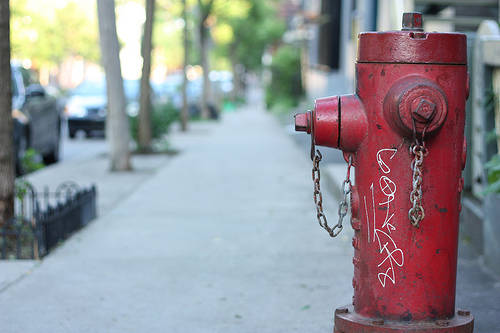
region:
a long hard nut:
[279, 70, 312, 147]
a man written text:
[377, 147, 427, 294]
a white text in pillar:
[363, 130, 422, 317]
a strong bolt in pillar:
[393, 82, 443, 128]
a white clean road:
[16, 80, 343, 327]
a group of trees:
[95, 25, 237, 128]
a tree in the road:
[88, 10, 147, 204]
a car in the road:
[50, 71, 147, 143]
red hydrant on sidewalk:
[304, 19, 471, 323]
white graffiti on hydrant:
[350, 144, 443, 309]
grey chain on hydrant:
[383, 116, 427, 254]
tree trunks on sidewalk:
[97, 2, 172, 198]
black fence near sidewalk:
[26, 152, 123, 276]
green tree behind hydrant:
[256, 57, 303, 140]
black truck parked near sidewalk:
[1, 66, 77, 178]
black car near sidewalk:
[47, 50, 142, 151]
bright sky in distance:
[35, 4, 140, 56]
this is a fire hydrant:
[274, 7, 480, 331]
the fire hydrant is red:
[241, 18, 478, 328]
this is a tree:
[89, 9, 134, 180]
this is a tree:
[129, 4, 161, 152]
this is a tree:
[170, 13, 194, 133]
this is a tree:
[194, 17, 224, 122]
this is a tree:
[216, 22, 262, 124]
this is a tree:
[244, 13, 305, 111]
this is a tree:
[130, 85, 172, 145]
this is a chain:
[290, 120, 367, 238]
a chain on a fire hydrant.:
[394, 103, 442, 238]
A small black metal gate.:
[0, 172, 97, 262]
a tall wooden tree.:
[92, 0, 140, 177]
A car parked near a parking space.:
[9, 63, 68, 185]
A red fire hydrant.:
[284, 12, 479, 331]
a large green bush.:
[264, 38, 309, 117]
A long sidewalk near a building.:
[0, 103, 496, 330]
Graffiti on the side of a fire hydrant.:
[351, 145, 411, 290]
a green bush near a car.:
[124, 108, 178, 143]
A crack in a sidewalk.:
[0, 252, 52, 294]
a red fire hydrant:
[291, 9, 490, 331]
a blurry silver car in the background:
[0, 62, 74, 176]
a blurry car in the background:
[61, 72, 146, 137]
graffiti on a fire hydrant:
[361, 142, 411, 292]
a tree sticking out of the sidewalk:
[89, 0, 143, 181]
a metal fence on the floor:
[0, 178, 108, 263]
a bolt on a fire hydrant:
[335, 302, 352, 315]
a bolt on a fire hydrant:
[368, 314, 384, 327]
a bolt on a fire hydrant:
[430, 318, 452, 329]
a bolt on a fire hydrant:
[456, 307, 472, 319]